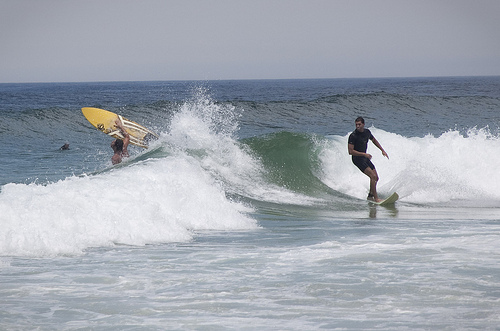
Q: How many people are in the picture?
A: 2.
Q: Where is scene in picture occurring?
A: In the ocean.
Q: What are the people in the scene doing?
A: Surfboarding.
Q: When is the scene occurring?
A: During the day.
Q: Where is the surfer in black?
A: On the right riding wave.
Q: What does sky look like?
A: Clear and blue.